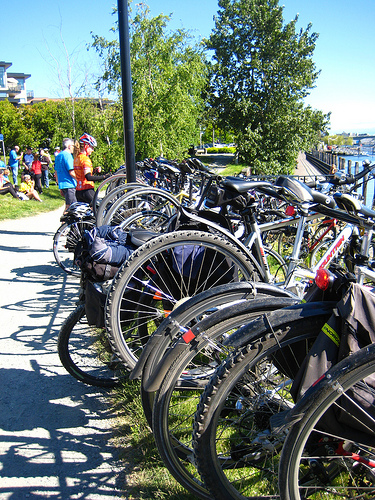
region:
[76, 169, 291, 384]
Bikes lined up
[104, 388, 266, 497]
The bikes are in the grass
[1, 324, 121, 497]
Shadow of bikes on the pavement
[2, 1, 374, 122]
The sky is blue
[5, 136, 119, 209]
Bikers near each other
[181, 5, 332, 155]
Trees in the back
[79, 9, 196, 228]
A pole in the middle of the picture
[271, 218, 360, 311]
Reflector on the bike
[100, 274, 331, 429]
Bike tires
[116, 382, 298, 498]
The grass is green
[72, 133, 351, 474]
the bikes are parked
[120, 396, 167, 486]
the grass is green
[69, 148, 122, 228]
the shirt is orange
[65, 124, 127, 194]
the person is wearing a helmet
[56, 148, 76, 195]
the shirt is blue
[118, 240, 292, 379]
the tire is black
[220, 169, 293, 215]
the seat is black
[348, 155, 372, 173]
the water is blue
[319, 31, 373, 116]
sky is blue and white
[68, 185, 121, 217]
the shorts are black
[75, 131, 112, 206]
a bike rider with a helmet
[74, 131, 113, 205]
man dressed as a bike rider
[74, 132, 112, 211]
a person dressed to ride a bike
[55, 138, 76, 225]
a man with a blue shirt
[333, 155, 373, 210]
a body of water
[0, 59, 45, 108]
buildings on the left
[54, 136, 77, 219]
a man with a gray hair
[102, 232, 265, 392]
rear tire on a bicycle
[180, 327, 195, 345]
red reflector on a bike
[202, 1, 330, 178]
a tree by the water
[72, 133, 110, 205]
person in helmet and orange shirt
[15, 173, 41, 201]
woman sitting on grass in a yellow shirt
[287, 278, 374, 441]
black bag hanging on bike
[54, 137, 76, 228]
man in blue shirts and shorts walking on sidewalk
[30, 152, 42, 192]
person standing wearing red shirt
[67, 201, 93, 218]
bike helmet on back of bike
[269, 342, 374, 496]
partial bike tire in front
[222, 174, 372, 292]
silver bike with Century in red letters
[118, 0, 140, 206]
black pole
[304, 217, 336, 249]
red bike frame with yellow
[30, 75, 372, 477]
row of bikes in a bike rack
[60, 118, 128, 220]
woman with a helmet and orange shirt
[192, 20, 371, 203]
green tree near the water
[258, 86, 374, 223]
board walk dock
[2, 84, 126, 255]
crowd of people near bikes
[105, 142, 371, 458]
red and white bike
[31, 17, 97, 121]
tree with no leaves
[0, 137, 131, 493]
bike shadows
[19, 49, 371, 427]
people standing near a beach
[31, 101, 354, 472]
a lot of parked bikes near people